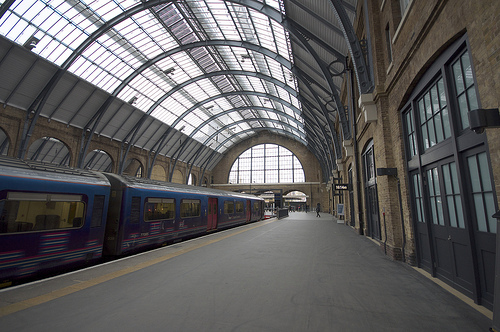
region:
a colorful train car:
[0, 161, 110, 280]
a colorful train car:
[110, 175, 215, 252]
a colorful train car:
[217, 182, 251, 228]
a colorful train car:
[250, 193, 267, 223]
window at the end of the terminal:
[237, 169, 252, 184]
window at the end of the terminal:
[265, 156, 280, 171]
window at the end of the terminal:
[280, 166, 295, 181]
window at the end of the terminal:
[227, 140, 304, 184]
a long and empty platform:
[0, 217, 492, 329]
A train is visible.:
[94, 175, 186, 319]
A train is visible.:
[60, 81, 191, 289]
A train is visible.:
[54, 158, 144, 288]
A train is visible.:
[92, 122, 159, 249]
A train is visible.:
[48, 134, 126, 246]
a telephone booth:
[333, 182, 350, 226]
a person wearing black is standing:
[313, 193, 326, 215]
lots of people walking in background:
[282, 182, 313, 219]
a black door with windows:
[428, 150, 483, 303]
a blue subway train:
[0, 170, 112, 280]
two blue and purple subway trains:
[3, 170, 270, 272]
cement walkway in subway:
[86, 197, 431, 317]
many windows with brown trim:
[387, 35, 477, 165]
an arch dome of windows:
[4, 0, 371, 151]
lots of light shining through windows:
[6, 2, 309, 177]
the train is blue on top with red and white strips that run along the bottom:
[0, 161, 268, 291]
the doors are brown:
[400, 25, 496, 315]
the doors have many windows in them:
[394, 42, 499, 292]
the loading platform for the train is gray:
[1, 200, 491, 330]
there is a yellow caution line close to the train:
[1, 167, 280, 320]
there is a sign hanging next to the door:
[328, 181, 358, 193]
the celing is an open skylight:
[0, 0, 330, 160]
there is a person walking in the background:
[315, 200, 325, 216]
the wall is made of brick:
[328, 0, 499, 274]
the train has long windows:
[4, 188, 92, 232]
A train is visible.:
[90, 171, 297, 316]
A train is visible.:
[87, 165, 235, 270]